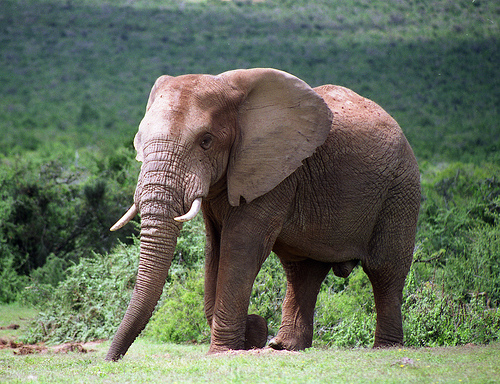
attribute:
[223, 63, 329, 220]
ear — huge, gray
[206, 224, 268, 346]
leg — gray, large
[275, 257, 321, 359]
leg — large, gray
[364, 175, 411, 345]
leg — large, gray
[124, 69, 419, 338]
elephant — one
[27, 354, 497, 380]
field — large, green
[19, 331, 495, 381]
grass — large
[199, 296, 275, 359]
leg — bent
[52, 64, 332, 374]
head — large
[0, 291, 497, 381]
field — green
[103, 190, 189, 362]
elephant trunk — grey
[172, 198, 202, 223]
elephant tusk — white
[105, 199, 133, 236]
elephant tusk — white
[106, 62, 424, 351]
elephant — one, grey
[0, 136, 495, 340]
trees — green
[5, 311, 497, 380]
field — green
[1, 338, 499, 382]
grass — short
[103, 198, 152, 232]
elephant tusk — large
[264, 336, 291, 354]
toenail — one, elephant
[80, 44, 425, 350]
elephant — grey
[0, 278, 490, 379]
grass — green , low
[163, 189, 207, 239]
tusk — large, elephant